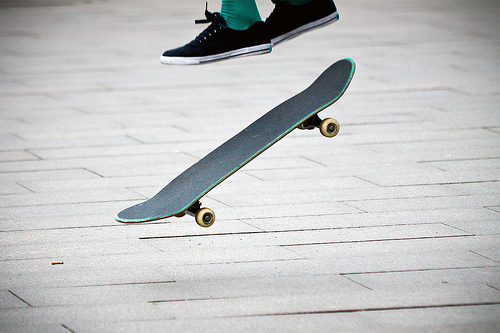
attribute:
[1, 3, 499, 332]
floor — stone, tile, brick, concrete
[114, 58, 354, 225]
skateboard — black, green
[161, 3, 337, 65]
shoes — black, white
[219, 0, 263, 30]
socks — green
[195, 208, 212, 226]
wheel — white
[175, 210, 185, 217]
wheel — white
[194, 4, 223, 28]
laces — black